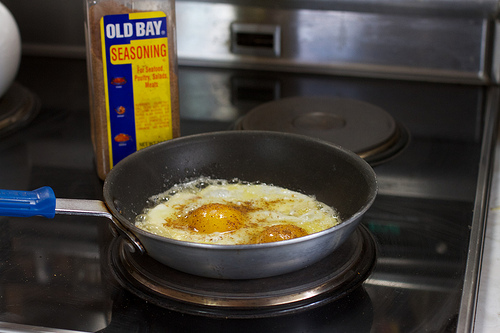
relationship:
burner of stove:
[237, 93, 410, 166] [0, 54, 499, 333]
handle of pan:
[0, 184, 106, 217] [102, 129, 376, 280]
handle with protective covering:
[0, 184, 106, 217] [2, 186, 55, 215]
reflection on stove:
[175, 1, 381, 67] [0, 54, 499, 333]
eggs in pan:
[133, 181, 338, 247] [102, 129, 376, 280]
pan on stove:
[102, 129, 376, 280] [0, 54, 499, 333]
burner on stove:
[237, 93, 410, 166] [0, 54, 499, 333]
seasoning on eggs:
[187, 200, 284, 242] [133, 181, 338, 247]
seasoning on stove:
[82, 0, 180, 181] [0, 54, 499, 333]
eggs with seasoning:
[133, 181, 338, 247] [187, 200, 284, 242]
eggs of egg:
[179, 199, 251, 234] [169, 192, 239, 244]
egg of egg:
[245, 220, 313, 244] [251, 190, 321, 245]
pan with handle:
[102, 129, 376, 280] [0, 184, 106, 217]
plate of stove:
[115, 269, 361, 303] [0, 54, 499, 333]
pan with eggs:
[102, 129, 376, 280] [133, 181, 338, 247]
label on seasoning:
[99, 11, 170, 175] [82, 0, 180, 181]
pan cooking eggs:
[102, 129, 376, 280] [133, 181, 338, 247]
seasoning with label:
[82, 0, 180, 181] [99, 11, 170, 175]